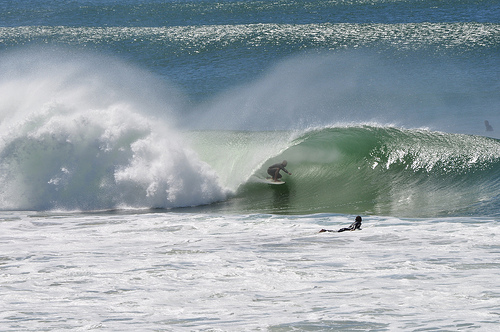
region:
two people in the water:
[63, 50, 434, 290]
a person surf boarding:
[213, 123, 420, 274]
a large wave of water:
[59, 40, 424, 305]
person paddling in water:
[306, 207, 378, 243]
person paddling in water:
[304, 210, 371, 245]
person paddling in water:
[315, 212, 372, 244]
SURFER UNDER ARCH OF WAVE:
[253, 158, 303, 186]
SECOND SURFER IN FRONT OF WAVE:
[335, 206, 364, 239]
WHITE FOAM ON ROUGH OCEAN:
[23, 223, 434, 324]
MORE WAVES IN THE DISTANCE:
[23, 6, 496, 154]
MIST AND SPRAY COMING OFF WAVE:
[11, 84, 191, 194]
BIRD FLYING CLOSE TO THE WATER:
[480, 116, 499, 136]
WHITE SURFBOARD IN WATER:
[271, 177, 290, 191]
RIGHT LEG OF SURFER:
[270, 165, 285, 180]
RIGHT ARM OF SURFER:
[282, 166, 299, 174]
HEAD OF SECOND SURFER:
[348, 197, 380, 224]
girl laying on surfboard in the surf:
[315, 208, 367, 237]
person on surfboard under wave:
[267, 157, 292, 194]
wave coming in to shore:
[183, 130, 479, 222]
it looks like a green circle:
[177, 128, 482, 212]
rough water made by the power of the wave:
[13, 113, 216, 208]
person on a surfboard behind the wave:
[471, 113, 495, 137]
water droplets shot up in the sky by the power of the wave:
[4, 16, 492, 73]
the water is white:
[15, 214, 497, 326]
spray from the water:
[228, 46, 483, 123]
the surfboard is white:
[267, 177, 287, 190]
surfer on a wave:
[244, 136, 313, 209]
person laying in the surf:
[309, 208, 384, 240]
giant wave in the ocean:
[16, 13, 498, 97]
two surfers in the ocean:
[249, 146, 395, 246]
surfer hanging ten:
[245, 131, 312, 221]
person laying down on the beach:
[304, 203, 386, 253]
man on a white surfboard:
[239, 141, 305, 217]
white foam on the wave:
[19, 78, 228, 233]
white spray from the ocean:
[8, 51, 130, 98]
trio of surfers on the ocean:
[115, 113, 498, 251]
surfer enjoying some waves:
[142, 91, 319, 211]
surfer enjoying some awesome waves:
[170, 113, 310, 215]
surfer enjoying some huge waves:
[149, 97, 314, 220]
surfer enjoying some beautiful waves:
[159, 88, 333, 220]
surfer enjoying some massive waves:
[174, 116, 322, 215]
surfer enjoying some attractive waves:
[202, 116, 324, 220]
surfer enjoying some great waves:
[120, 87, 347, 214]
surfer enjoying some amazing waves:
[76, 38, 339, 211]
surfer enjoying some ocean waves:
[146, 96, 346, 209]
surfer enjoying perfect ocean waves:
[156, 105, 353, 205]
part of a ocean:
[403, 190, 442, 215]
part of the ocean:
[301, 290, 308, 297]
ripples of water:
[425, 265, 453, 277]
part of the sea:
[373, 251, 405, 296]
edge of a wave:
[126, 181, 139, 211]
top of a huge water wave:
[420, 212, 431, 242]